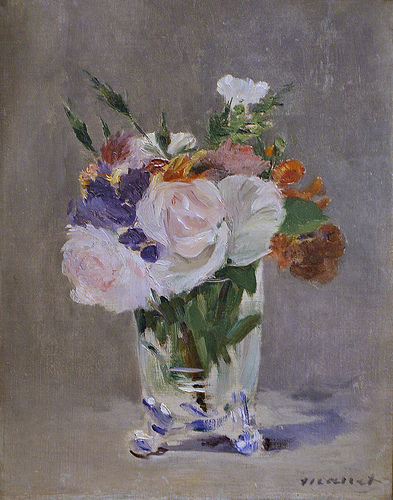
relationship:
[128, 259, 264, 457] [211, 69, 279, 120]
vase full of flower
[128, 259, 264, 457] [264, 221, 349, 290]
vase full of flower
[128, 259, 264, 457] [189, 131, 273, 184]
vase full of flower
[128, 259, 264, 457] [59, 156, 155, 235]
vase full of flower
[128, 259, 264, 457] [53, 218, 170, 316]
vase full of flower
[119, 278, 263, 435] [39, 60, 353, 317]
vase full of flowers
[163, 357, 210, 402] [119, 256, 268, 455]
light reflected off glass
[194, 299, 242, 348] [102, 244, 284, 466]
leaves in vase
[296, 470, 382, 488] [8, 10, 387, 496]
writing on picture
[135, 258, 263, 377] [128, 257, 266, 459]
leaves in vase